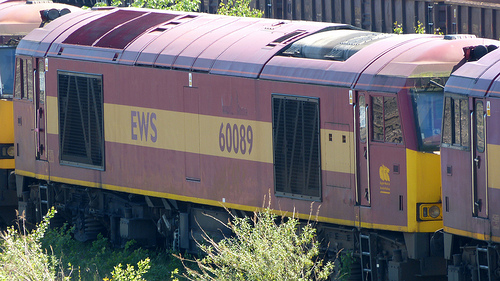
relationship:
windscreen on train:
[416, 93, 443, 150] [14, 5, 444, 259]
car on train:
[13, 4, 493, 265] [0, 9, 499, 268]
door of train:
[352, 88, 405, 227] [14, 5, 444, 259]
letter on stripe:
[128, 109, 139, 140] [46, 94, 355, 173]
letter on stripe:
[137, 110, 152, 141] [46, 94, 355, 173]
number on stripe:
[217, 119, 225, 152] [46, 94, 355, 173]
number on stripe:
[246, 123, 254, 155] [46, 94, 355, 173]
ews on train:
[128, 107, 159, 142] [14, 5, 444, 259]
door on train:
[268, 94, 324, 201] [14, 5, 444, 259]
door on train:
[54, 69, 106, 172] [14, 5, 444, 259]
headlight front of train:
[428, 202, 441, 220] [14, 5, 444, 259]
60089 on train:
[218, 123, 256, 155] [14, 5, 444, 259]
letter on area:
[128, 109, 139, 140] [46, 94, 355, 173]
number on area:
[217, 119, 225, 152] [46, 94, 355, 173]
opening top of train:
[281, 24, 390, 61] [14, 5, 444, 259]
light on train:
[428, 202, 441, 220] [14, 5, 444, 259]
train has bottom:
[14, 5, 444, 259] [14, 174, 443, 280]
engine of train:
[13, 4, 493, 265] [0, 9, 499, 268]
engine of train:
[0, 0, 88, 209] [0, 9, 499, 268]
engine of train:
[440, 42, 499, 281] [0, 9, 499, 268]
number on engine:
[217, 119, 225, 152] [13, 4, 493, 265]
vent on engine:
[265, 28, 307, 49] [13, 4, 493, 265]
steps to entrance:
[355, 233, 375, 278] [352, 88, 405, 227]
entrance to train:
[352, 88, 405, 227] [14, 5, 444, 259]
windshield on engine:
[0, 46, 17, 98] [0, 0, 88, 209]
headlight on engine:
[6, 144, 17, 157] [0, 0, 88, 209]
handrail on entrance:
[350, 102, 361, 208] [352, 88, 405, 227]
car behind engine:
[439, 0, 499, 41] [440, 42, 499, 281]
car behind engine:
[267, 0, 438, 33] [14, 5, 444, 259]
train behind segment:
[67, 1, 499, 38] [14, 5, 444, 259]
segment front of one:
[440, 42, 499, 281] [14, 5, 444, 259]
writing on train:
[128, 107, 258, 156] [14, 5, 444, 259]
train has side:
[14, 5, 444, 259] [15, 53, 409, 227]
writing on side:
[128, 107, 258, 156] [15, 53, 409, 227]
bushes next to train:
[2, 203, 356, 281] [0, 9, 499, 268]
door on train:
[352, 88, 405, 227] [14, 5, 444, 259]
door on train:
[443, 92, 489, 240] [0, 9, 499, 268]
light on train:
[6, 144, 17, 157] [0, 9, 499, 268]